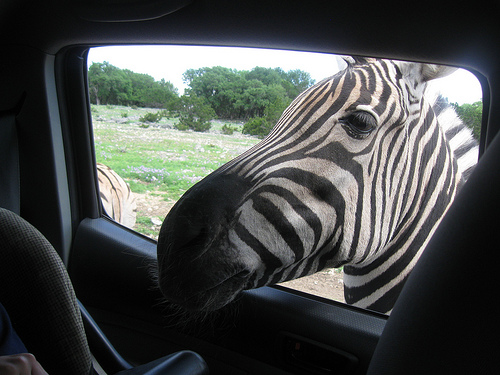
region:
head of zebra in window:
[141, 54, 488, 328]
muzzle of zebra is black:
[148, 165, 265, 322]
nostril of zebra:
[174, 217, 219, 264]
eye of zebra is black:
[334, 103, 380, 140]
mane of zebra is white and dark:
[422, 85, 479, 182]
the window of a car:
[56, 25, 498, 330]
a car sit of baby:
[0, 208, 210, 374]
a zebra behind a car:
[74, 152, 146, 237]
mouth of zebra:
[150, 263, 247, 328]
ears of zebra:
[341, 54, 452, 84]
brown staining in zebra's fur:
[311, 72, 401, 117]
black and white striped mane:
[422, 85, 482, 180]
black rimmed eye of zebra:
[344, 103, 378, 143]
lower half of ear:
[398, 58, 455, 83]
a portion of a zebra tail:
[108, 188, 124, 223]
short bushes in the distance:
[115, 102, 237, 131]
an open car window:
[54, 28, 494, 324]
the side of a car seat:
[0, 205, 91, 371]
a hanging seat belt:
[40, 69, 67, 251]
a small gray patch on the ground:
[129, 164, 165, 186]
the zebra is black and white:
[123, 65, 439, 321]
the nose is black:
[132, 195, 229, 263]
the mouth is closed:
[126, 245, 263, 332]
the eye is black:
[330, 110, 392, 138]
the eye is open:
[333, 91, 393, 146]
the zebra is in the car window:
[131, 46, 401, 315]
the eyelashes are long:
[328, 92, 381, 141]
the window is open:
[37, 27, 403, 268]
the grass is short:
[114, 121, 184, 189]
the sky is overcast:
[100, 43, 282, 121]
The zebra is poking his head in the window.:
[128, 26, 474, 335]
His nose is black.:
[140, 202, 247, 291]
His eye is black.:
[321, 102, 376, 149]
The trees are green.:
[78, 57, 308, 122]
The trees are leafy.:
[85, 54, 327, 143]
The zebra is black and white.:
[134, 51, 492, 340]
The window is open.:
[2, 6, 493, 373]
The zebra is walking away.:
[91, 136, 153, 243]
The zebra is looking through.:
[7, 9, 478, 374]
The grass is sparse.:
[96, 105, 230, 216]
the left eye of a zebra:
[343, 108, 375, 142]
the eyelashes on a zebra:
[355, 105, 381, 127]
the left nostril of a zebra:
[177, 225, 209, 254]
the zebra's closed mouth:
[160, 274, 236, 302]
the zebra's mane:
[424, 86, 478, 181]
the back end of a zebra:
[94, 163, 138, 231]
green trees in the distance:
[87, 58, 487, 155]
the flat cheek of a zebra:
[336, 162, 410, 258]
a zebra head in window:
[128, 41, 485, 351]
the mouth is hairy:
[143, 253, 243, 349]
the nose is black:
[138, 178, 258, 271]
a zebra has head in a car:
[148, 58, 448, 333]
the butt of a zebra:
[87, 117, 162, 229]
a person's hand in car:
[1, 339, 56, 374]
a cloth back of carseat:
[0, 201, 85, 354]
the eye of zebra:
[333, 106, 385, 138]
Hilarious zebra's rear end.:
[80, 150, 145, 239]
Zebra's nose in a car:
[148, 160, 278, 322]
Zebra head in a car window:
[146, 33, 494, 357]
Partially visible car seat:
[2, 203, 219, 373]